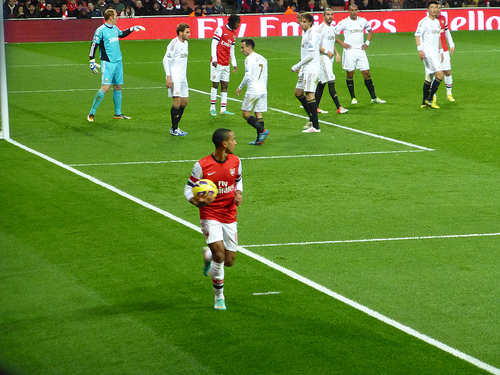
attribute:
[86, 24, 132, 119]
outfit — blue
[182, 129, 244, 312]
man — standing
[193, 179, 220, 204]
ball — yellow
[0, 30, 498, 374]
grass — green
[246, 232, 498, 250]
lines — white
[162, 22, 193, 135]
player — standing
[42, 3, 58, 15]
spectator — stands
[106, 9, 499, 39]
wall — red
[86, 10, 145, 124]
uniform — blue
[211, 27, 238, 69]
uniform — red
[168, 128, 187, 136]
shoe — blue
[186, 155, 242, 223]
shirt — red